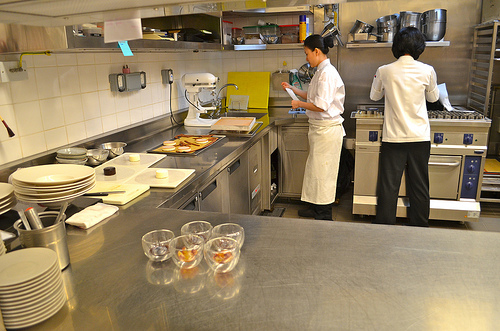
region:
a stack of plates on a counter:
[3, 244, 68, 326]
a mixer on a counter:
[180, 68, 223, 130]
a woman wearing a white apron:
[281, 30, 351, 222]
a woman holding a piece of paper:
[278, 35, 348, 136]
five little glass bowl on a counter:
[140, 215, 248, 270]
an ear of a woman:
[313, 45, 323, 60]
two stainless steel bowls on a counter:
[86, 138, 124, 159]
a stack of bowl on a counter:
[48, 145, 89, 163]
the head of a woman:
[295, 32, 340, 68]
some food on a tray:
[151, 126, 226, 155]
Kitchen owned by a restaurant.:
[6, 7, 493, 329]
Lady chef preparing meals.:
[279, 30, 347, 219]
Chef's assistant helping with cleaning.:
[371, 25, 441, 231]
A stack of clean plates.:
[2, 246, 72, 329]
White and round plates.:
[3, 249, 64, 329]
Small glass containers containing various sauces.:
[140, 208, 252, 270]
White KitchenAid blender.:
[183, 68, 216, 129]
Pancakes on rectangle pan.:
[153, 130, 228, 155]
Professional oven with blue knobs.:
[352, 102, 490, 220]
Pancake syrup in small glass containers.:
[172, 235, 240, 271]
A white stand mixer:
[178, 70, 219, 128]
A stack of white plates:
[1, 243, 71, 329]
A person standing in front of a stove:
[356, 24, 490, 221]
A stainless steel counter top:
[246, 206, 497, 326]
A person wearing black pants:
[376, 140, 433, 222]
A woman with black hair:
[300, 33, 336, 68]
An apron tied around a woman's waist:
[294, 115, 345, 208]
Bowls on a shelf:
[345, 6, 453, 51]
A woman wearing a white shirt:
[301, 58, 346, 120]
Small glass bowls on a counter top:
[136, 217, 252, 278]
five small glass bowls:
[135, 213, 251, 281]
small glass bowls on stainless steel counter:
[139, 211, 251, 278]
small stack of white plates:
[10, 160, 101, 205]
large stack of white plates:
[0, 246, 80, 328]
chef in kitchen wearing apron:
[281, 32, 358, 219]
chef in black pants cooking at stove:
[369, 23, 451, 225]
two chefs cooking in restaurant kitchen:
[276, 21, 441, 226]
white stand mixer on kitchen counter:
[179, 66, 226, 131]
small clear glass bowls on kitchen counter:
[136, 216, 253, 276]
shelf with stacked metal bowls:
[348, 8, 450, 45]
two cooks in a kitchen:
[134, 16, 495, 248]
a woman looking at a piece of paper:
[271, 32, 346, 121]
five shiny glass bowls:
[141, 214, 248, 272]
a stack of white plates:
[1, 240, 71, 329]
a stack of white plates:
[5, 159, 102, 196]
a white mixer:
[177, 68, 229, 132]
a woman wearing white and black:
[364, 17, 464, 222]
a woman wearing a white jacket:
[368, 18, 453, 153]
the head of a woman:
[388, 22, 430, 64]